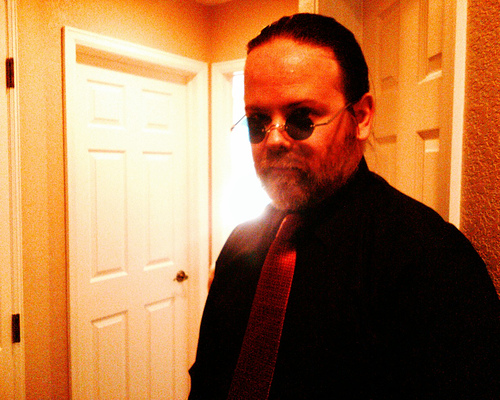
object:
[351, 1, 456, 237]
door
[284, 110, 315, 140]
lenses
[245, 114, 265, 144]
lenses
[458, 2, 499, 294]
textured wall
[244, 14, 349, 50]
dark hair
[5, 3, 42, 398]
trim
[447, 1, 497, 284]
wall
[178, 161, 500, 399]
dress shirt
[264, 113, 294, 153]
nose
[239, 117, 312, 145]
black sunglasses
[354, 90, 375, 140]
ear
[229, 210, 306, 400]
necktie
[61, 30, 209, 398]
door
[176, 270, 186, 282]
handle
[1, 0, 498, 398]
hallway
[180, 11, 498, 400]
man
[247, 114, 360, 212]
beard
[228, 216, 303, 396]
tie